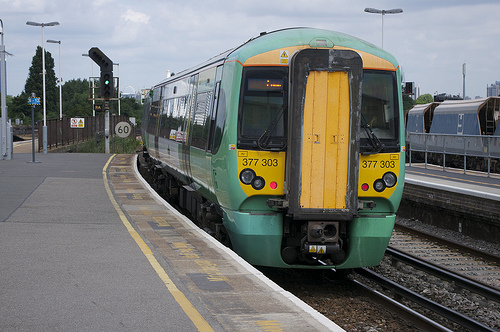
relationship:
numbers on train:
[362, 160, 394, 169] [140, 25, 410, 274]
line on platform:
[101, 152, 215, 330] [2, 147, 347, 329]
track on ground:
[342, 181, 500, 332] [257, 210, 498, 327]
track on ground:
[385, 243, 498, 299] [257, 210, 498, 327]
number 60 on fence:
[116, 118, 129, 137] [34, 105, 136, 149]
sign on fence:
[64, 110, 96, 139] [35, 113, 132, 152]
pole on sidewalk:
[28, 103, 40, 164] [2, 147, 301, 329]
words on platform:
[166, 225, 241, 313] [71, 176, 148, 313]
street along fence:
[9, 122, 43, 153] [44, 116, 121, 152]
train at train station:
[140, 25, 410, 274] [285, 40, 457, 285]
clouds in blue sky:
[0, 3, 499, 101] [0, 0, 500, 98]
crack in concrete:
[0, 217, 123, 227] [1, 150, 345, 330]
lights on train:
[241, 154, 268, 186] [166, 13, 409, 311]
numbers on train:
[359, 152, 404, 174] [140, 25, 410, 274]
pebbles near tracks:
[316, 290, 392, 330] [346, 268, 498, 328]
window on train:
[235, 71, 312, 146] [83, 27, 436, 272]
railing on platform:
[407, 133, 498, 179] [17, 144, 496, 328]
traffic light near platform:
[84, 45, 121, 105] [0, 127, 367, 329]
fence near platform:
[24, 109, 139, 154] [2, 147, 347, 329]